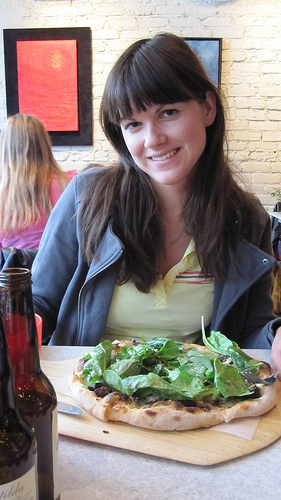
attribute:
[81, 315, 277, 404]
spinach — green, piled, purple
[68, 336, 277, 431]
pizza — whole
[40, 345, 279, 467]
board — wood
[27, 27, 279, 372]
woman — posing, looking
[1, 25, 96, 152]
picture — red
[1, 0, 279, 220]
wall — brick, yellow, white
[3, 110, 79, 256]
woman — blonde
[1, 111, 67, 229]
hair — blonde, long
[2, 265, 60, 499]
bottle — brown, glass, half full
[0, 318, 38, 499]
bottle — brown, glass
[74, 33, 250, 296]
hair — long, dark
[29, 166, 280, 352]
jacket — blue, longsleeved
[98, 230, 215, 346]
shirt — yellow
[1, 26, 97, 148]
frame — black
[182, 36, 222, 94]
picture — blue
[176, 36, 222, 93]
frame — black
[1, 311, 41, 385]
cup — red, small